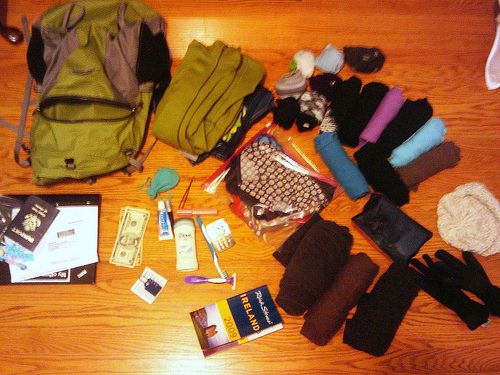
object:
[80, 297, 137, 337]
floor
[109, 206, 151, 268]
money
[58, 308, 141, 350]
floor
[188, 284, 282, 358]
book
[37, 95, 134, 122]
compartment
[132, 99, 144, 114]
zipper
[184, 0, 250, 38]
floor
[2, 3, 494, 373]
items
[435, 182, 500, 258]
hat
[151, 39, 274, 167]
bottoms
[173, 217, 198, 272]
deodorant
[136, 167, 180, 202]
bag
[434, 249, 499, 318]
black gloves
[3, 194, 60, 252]
passport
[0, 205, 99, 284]
paper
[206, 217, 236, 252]
medication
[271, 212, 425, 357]
collection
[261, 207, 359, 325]
shirt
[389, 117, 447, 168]
shirt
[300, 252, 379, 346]
shirt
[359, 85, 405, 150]
shirt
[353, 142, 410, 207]
shirt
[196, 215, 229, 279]
toothbrush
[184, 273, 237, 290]
razor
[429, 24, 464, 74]
floor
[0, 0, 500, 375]
floor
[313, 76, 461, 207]
clothes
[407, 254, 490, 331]
gloves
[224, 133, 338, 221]
ziploc bag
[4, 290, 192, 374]
floor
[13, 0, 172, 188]
backpack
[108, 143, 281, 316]
items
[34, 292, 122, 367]
wooden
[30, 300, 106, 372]
floor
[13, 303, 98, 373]
floor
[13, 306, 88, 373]
table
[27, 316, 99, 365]
table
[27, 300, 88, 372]
table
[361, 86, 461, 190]
socks